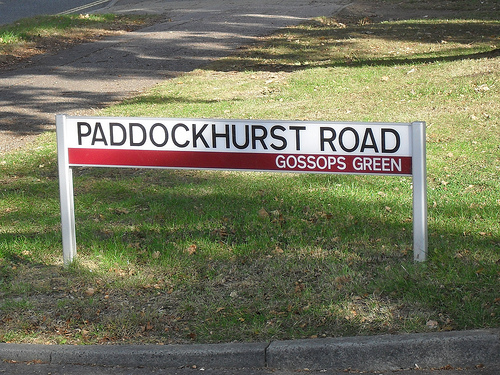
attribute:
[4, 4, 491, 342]
grass — green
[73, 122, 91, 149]
letter — black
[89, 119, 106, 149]
letter — black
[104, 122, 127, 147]
letter — black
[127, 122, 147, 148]
letter — black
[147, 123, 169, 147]
letter — black, o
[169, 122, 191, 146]
letter — black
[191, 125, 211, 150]
letter — black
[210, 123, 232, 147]
letter — black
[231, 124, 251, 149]
letter — black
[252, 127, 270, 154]
letter — black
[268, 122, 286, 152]
letter — black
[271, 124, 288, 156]
letter — black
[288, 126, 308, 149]
letter — black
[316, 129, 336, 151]
letter — black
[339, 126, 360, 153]
letter — black, o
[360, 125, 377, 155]
letter — black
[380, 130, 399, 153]
letter — black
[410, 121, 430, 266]
pole — short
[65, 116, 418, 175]
text — black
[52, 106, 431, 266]
sign — red, white, black, paddockhurst road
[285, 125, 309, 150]
black letter — t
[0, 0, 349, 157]
path — concrete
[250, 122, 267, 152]
black letter — r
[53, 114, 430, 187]
sign — white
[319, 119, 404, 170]
writing — black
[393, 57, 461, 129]
grass — green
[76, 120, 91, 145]
letter — p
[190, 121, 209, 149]
letter — black, k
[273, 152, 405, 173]
text — white